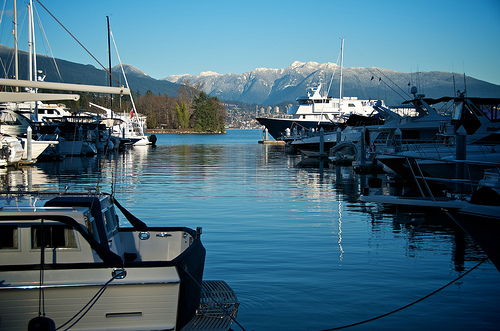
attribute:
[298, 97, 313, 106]
window — glass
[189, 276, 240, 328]
deck — small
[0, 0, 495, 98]
sky — bright blue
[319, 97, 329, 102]
window — glass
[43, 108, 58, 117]
window — glass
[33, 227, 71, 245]
window — glass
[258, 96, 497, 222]
boats — together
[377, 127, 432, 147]
window — glass